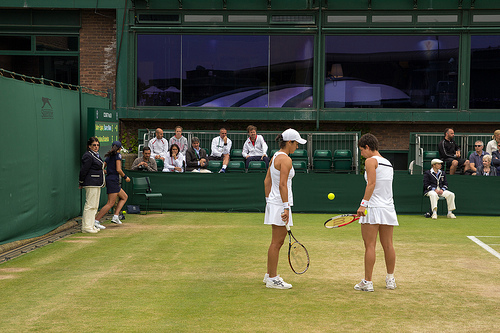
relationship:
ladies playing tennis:
[261, 124, 402, 291] [260, 126, 403, 292]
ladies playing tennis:
[81, 134, 127, 231] [260, 126, 403, 292]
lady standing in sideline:
[75, 134, 105, 239] [0, 196, 130, 279]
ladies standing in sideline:
[94, 141, 130, 229] [0, 196, 130, 279]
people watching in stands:
[121, 95, 285, 210] [114, 119, 499, 219]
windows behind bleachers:
[135, 41, 490, 93] [142, 114, 292, 186]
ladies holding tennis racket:
[262, 128, 307, 290] [283, 224, 310, 274]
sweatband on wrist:
[358, 197, 367, 215] [357, 194, 369, 216]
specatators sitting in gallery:
[129, 123, 270, 173] [117, 120, 361, 176]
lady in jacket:
[79, 136, 106, 233] [82, 150, 110, 185]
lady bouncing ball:
[353, 133, 399, 292] [324, 190, 339, 204]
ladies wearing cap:
[262, 128, 307, 290] [280, 125, 310, 144]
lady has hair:
[353, 133, 399, 292] [359, 130, 381, 145]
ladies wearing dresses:
[262, 128, 307, 290] [260, 195, 402, 229]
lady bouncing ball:
[353, 133, 399, 292] [327, 192, 336, 200]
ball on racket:
[327, 192, 336, 200] [321, 210, 363, 230]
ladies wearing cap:
[262, 128, 307, 290] [276, 126, 305, 148]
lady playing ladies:
[353, 133, 399, 292] [262, 128, 307, 290]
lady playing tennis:
[353, 133, 399, 292] [226, 110, 463, 299]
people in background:
[142, 120, 494, 186] [81, 66, 465, 195]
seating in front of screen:
[131, 142, 499, 177] [114, 162, 498, 214]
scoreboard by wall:
[85, 106, 121, 143] [7, 81, 79, 229]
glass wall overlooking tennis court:
[127, 6, 499, 122] [0, 205, 496, 332]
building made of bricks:
[2, 1, 498, 214] [75, 14, 116, 89]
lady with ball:
[317, 127, 409, 302] [321, 188, 337, 201]